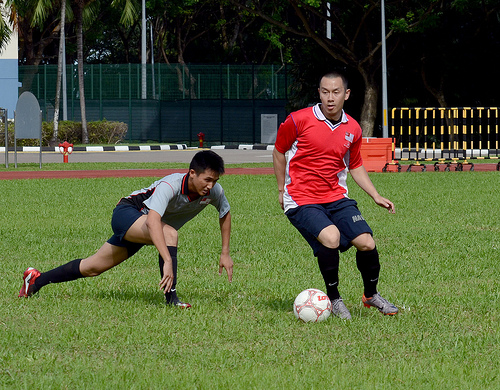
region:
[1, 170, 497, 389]
Grass beneath the players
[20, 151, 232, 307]
A player falling towards the ground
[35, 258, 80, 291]
The player is wearing black socks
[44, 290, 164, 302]
A shadow on the grass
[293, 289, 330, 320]
A soccer ball on the field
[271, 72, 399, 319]
The player has control of hte ball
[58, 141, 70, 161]
A hydrant by the street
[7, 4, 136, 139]
Trees on the grass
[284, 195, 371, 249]
The player is wearing blue shorts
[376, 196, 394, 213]
The left hand of the man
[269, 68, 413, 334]
player on the field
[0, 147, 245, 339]
player on the field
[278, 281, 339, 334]
soccer ball on the field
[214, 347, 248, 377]
patch of green grass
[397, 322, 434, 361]
patch of green grass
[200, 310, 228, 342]
patch of green grass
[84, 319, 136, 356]
patch of green grass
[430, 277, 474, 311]
patch of green grass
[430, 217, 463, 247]
patch of green grass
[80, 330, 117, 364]
patch of green grass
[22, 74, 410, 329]
two men that are playing socker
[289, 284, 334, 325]
a white and red soccer ball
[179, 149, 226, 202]
the head of a man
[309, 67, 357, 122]
the head of a man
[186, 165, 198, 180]
the ear of a man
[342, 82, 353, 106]
the ear of a man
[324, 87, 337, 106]
the nose of a man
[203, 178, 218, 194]
the nose of a man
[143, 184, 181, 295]
the arm of a man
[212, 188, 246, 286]
the arm of a man